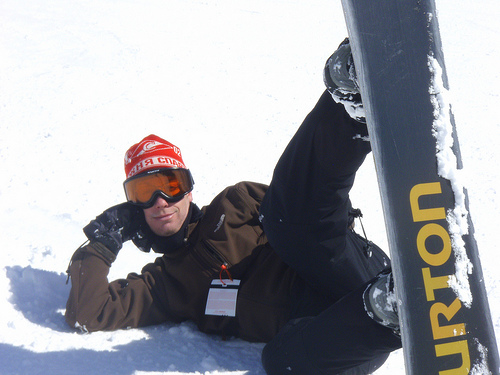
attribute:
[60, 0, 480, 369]
man — close, happy, lying, white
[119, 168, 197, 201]
goggles — big, orange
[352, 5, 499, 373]
board — black, thin, skinny, long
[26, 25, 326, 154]
snow — white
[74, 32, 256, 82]
snow — white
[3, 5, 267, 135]
snow — white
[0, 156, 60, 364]
snow — white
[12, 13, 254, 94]
snow — white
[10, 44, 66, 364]
snow — white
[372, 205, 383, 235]
snow — white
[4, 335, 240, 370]
snow — white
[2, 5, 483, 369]
snow — white, thick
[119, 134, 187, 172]
beanie — red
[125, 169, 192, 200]
lens — orange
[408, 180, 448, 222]
letter — yellow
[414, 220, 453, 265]
letter — yellow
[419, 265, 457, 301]
letter — yellow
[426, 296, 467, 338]
letter — yellow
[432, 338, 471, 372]
letter — yellow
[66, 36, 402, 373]
man — snowboarder, posing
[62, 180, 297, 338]
jacket — brown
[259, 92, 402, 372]
pants — black